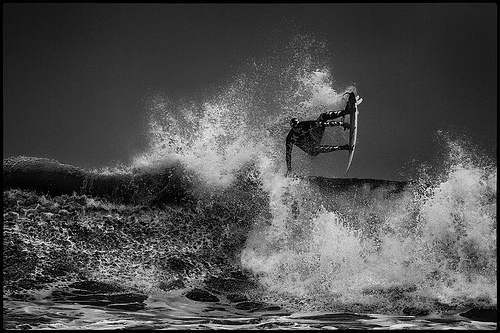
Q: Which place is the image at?
A: It is at the ocean.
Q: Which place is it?
A: It is an ocean.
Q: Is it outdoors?
A: Yes, it is outdoors.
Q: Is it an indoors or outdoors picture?
A: It is outdoors.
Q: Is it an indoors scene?
A: No, it is outdoors.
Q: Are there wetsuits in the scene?
A: Yes, there is a wetsuit.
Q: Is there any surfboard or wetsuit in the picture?
A: Yes, there is a wetsuit.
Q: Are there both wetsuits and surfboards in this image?
A: Yes, there are both a wetsuit and a surfboard.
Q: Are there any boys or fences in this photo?
A: No, there are no boys or fences.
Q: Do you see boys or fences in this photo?
A: No, there are no boys or fences.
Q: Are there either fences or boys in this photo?
A: No, there are no boys or fences.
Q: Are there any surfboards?
A: Yes, there is a surfboard.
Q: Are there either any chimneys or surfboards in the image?
A: Yes, there is a surfboard.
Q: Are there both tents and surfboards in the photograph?
A: No, there is a surfboard but no tents.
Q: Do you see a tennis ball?
A: No, there are no tennis balls.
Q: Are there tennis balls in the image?
A: No, there are no tennis balls.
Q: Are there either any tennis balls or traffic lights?
A: No, there are no tennis balls or traffic lights.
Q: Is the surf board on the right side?
A: Yes, the surf board is on the right of the image.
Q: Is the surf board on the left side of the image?
A: No, the surf board is on the right of the image.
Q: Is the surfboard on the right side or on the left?
A: The surfboard is on the right of the image.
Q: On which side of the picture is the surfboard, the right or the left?
A: The surfboard is on the right of the image.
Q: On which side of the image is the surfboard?
A: The surfboard is on the right of the image.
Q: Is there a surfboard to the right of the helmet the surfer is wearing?
A: Yes, there is a surfboard to the right of the helmet.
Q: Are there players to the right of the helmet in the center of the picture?
A: No, there is a surfboard to the right of the helmet.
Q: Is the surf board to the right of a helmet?
A: Yes, the surf board is to the right of a helmet.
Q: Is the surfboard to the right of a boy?
A: No, the surfboard is to the right of a helmet.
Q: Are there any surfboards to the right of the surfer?
A: Yes, there is a surfboard to the right of the surfer.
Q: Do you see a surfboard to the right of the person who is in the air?
A: Yes, there is a surfboard to the right of the surfer.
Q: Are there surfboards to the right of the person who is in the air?
A: Yes, there is a surfboard to the right of the surfer.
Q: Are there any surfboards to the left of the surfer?
A: No, the surfboard is to the right of the surfer.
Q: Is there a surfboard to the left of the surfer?
A: No, the surfboard is to the right of the surfer.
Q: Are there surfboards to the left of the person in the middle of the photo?
A: No, the surfboard is to the right of the surfer.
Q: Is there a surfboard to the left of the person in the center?
A: No, the surfboard is to the right of the surfer.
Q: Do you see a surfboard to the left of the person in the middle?
A: No, the surfboard is to the right of the surfer.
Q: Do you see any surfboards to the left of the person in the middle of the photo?
A: No, the surfboard is to the right of the surfer.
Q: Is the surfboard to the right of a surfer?
A: Yes, the surfboard is to the right of a surfer.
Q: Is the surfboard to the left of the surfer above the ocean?
A: No, the surfboard is to the right of the surfer.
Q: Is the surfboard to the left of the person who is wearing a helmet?
A: No, the surfboard is to the right of the surfer.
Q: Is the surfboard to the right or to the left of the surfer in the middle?
A: The surfboard is to the right of the surfer.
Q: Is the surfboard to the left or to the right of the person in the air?
A: The surfboard is to the right of the surfer.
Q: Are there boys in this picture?
A: No, there are no boys.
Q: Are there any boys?
A: No, there are no boys.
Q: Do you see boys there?
A: No, there are no boys.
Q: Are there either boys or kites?
A: No, there are no boys or kites.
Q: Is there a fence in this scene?
A: No, there are no fences.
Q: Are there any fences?
A: No, there are no fences.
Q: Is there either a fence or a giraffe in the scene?
A: No, there are no fences or giraffes.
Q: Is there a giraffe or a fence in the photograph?
A: No, there are no fences or giraffes.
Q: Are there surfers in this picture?
A: Yes, there is a surfer.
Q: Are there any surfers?
A: Yes, there is a surfer.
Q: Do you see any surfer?
A: Yes, there is a surfer.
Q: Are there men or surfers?
A: Yes, there is a surfer.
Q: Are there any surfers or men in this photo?
A: Yes, there is a surfer.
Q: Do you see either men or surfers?
A: Yes, there is a surfer.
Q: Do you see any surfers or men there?
A: Yes, there is a surfer.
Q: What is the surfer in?
A: The surfer is in the air.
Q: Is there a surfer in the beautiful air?
A: Yes, there is a surfer in the air.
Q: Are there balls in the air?
A: No, there is a surfer in the air.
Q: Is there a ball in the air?
A: No, there is a surfer in the air.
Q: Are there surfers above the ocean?
A: Yes, there is a surfer above the ocean.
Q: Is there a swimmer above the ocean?
A: No, there is a surfer above the ocean.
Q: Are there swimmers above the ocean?
A: No, there is a surfer above the ocean.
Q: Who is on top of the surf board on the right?
A: The surfer is on top of the surfboard.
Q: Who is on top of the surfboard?
A: The surfer is on top of the surfboard.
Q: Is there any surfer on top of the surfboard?
A: Yes, there is a surfer on top of the surfboard.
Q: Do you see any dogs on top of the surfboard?
A: No, there is a surfer on top of the surfboard.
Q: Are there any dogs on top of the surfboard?
A: No, there is a surfer on top of the surfboard.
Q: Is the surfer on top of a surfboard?
A: Yes, the surfer is on top of a surfboard.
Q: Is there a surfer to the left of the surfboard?
A: Yes, there is a surfer to the left of the surfboard.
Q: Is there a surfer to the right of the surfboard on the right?
A: No, the surfer is to the left of the surf board.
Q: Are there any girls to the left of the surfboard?
A: No, there is a surfer to the left of the surfboard.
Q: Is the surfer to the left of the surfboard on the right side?
A: Yes, the surfer is to the left of the surfboard.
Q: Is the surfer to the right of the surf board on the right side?
A: No, the surfer is to the left of the surfboard.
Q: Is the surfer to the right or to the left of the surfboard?
A: The surfer is to the left of the surfboard.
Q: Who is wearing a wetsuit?
A: The surfer is wearing a wetsuit.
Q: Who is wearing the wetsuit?
A: The surfer is wearing a wetsuit.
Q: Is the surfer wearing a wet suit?
A: Yes, the surfer is wearing a wet suit.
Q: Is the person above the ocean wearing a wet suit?
A: Yes, the surfer is wearing a wet suit.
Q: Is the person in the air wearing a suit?
A: No, the surfer is wearing a wet suit.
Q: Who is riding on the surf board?
A: The surfer is riding on the surf board.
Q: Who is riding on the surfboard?
A: The surfer is riding on the surf board.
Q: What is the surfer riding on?
A: The surfer is riding on the surfboard.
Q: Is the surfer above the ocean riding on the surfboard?
A: Yes, the surfer is riding on the surfboard.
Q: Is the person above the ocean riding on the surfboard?
A: Yes, the surfer is riding on the surfboard.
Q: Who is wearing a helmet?
A: The surfer is wearing a helmet.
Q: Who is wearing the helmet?
A: The surfer is wearing a helmet.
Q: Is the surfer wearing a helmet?
A: Yes, the surfer is wearing a helmet.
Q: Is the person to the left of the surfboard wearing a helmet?
A: Yes, the surfer is wearing a helmet.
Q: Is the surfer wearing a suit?
A: No, the surfer is wearing a helmet.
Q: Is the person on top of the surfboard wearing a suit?
A: No, the surfer is wearing a helmet.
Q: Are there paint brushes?
A: No, there are no paint brushes.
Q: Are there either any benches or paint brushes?
A: No, there are no paint brushes or benches.